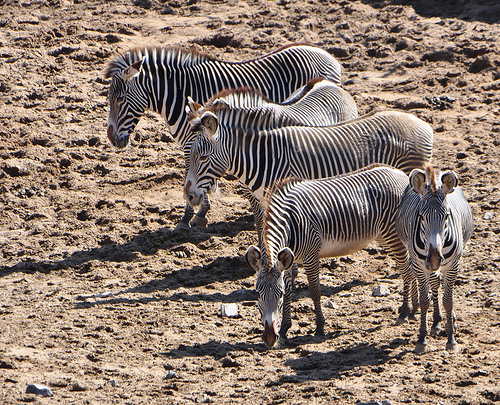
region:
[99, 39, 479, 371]
Gravy zebras on grassless ground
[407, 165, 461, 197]
Zebra ears facing forward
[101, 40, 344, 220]
The stallion of the herd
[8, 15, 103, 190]
Bare, dry and parched ground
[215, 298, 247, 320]
A rock on the ground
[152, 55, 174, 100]
The stripes of a zebra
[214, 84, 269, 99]
The mane of a zebra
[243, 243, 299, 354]
A zebra sniffing at the ground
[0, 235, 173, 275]
The shadow of a zebra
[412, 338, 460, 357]
The hooves of a zebra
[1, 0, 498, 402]
A dirt field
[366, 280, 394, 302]
A rock in the dirt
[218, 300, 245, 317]
A rock in the dirt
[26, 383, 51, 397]
A rock in the dirt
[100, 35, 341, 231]
A zebra standing in the dirt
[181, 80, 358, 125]
A zebra standing in the dirt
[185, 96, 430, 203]
A zebra standing in the dirt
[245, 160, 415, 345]
A zebra standing in the dirt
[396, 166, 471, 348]
A zebra standing in the dirt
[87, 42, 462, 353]
five zebras standing in the dirt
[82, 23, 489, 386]
zebras in the desert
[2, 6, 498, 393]
the ground is brown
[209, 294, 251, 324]
a rock on the ground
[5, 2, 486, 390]
the ground is rough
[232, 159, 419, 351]
the zebra is eating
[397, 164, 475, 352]
the zebra is facing forwards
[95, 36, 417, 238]
the zebras are looking sideways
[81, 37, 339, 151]
the zebra is striped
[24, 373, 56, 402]
the rock is grey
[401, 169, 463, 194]
zebra ears sticking up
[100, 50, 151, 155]
head of a zebra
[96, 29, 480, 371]
five zebras standing together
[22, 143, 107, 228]
clumps of dirt on ground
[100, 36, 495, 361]
zebras standing on dirt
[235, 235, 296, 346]
zebra with head towards ground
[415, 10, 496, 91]
clumps of brown dirt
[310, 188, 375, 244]
black and white stripes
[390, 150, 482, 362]
black and white zebra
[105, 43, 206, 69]
striped mane of zebra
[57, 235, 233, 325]
shadows on the ground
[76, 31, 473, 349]
Five zebras in a group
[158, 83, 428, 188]
Two zebras standing next to each other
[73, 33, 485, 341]
Numerous zebra stripes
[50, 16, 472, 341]
Zebras standing in dirt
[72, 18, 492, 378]
Five zebras standing in dirt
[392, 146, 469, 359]
A zebra looking straight ahead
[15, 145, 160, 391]
dirt on the ground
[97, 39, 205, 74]
A zebra mane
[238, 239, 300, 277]
Ears on a zebra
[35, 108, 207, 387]
Hoof prints in the dirt